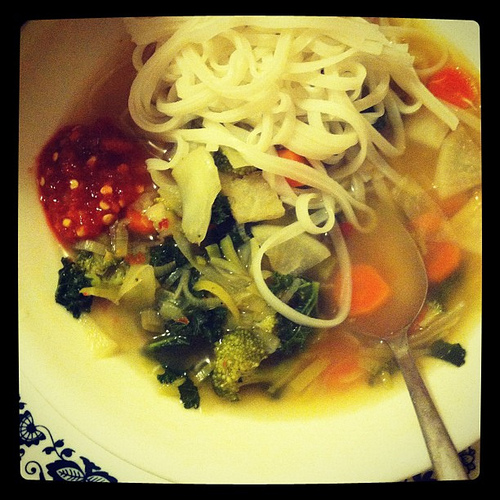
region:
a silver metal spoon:
[328, 195, 467, 480]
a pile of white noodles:
[122, 17, 451, 319]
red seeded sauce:
[39, 126, 144, 236]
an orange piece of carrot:
[337, 265, 384, 310]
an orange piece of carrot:
[313, 328, 365, 382]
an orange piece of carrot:
[414, 211, 464, 282]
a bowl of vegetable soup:
[40, 34, 479, 404]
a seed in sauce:
[100, 182, 112, 194]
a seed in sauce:
[67, 176, 81, 189]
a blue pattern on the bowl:
[17, 396, 118, 481]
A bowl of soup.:
[83, 59, 453, 356]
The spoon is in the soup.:
[305, 230, 465, 392]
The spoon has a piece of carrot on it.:
[334, 271, 401, 324]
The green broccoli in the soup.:
[180, 306, 317, 388]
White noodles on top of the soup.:
[168, 38, 382, 157]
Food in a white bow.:
[74, 71, 436, 376]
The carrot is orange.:
[321, 247, 436, 328]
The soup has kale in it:
[147, 262, 241, 366]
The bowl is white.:
[46, 317, 417, 450]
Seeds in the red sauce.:
[47, 124, 139, 219]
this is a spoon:
[403, 341, 451, 482]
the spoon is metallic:
[439, 440, 449, 482]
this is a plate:
[65, 390, 140, 439]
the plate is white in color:
[96, 422, 142, 452]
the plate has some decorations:
[22, 415, 89, 484]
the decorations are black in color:
[57, 461, 69, 466]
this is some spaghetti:
[199, 27, 306, 114]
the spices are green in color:
[113, 250, 243, 334]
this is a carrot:
[358, 267, 381, 299]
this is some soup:
[381, 223, 406, 252]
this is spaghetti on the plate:
[162, 28, 346, 138]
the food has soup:
[372, 242, 415, 312]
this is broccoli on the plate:
[192, 321, 258, 388]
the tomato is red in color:
[51, 124, 112, 223]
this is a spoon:
[404, 414, 469, 467]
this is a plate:
[273, 421, 342, 487]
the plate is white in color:
[180, 438, 245, 495]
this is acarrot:
[355, 273, 387, 311]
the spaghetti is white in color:
[222, 37, 299, 122]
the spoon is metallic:
[415, 403, 464, 454]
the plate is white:
[185, 421, 316, 484]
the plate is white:
[255, 411, 320, 463]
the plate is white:
[255, 440, 329, 488]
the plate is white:
[250, 408, 355, 479]